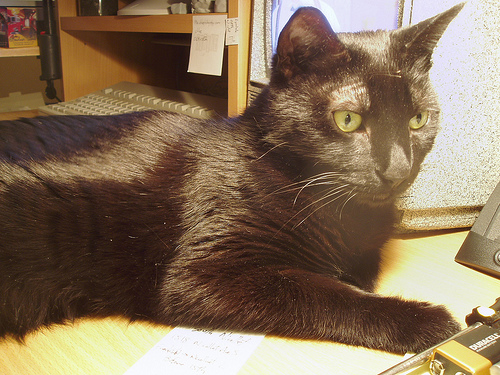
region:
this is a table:
[42, 344, 82, 361]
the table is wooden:
[53, 330, 78, 350]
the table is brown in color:
[56, 345, 88, 362]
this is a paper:
[171, 330, 208, 357]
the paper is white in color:
[153, 353, 163, 364]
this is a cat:
[23, 17, 453, 350]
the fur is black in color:
[132, 141, 221, 212]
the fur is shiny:
[88, 143, 165, 199]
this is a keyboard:
[55, 87, 182, 116]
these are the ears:
[282, 2, 459, 61]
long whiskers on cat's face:
[272, 171, 362, 212]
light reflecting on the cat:
[70, 120, 210, 189]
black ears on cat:
[261, 10, 359, 96]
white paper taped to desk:
[170, 8, 245, 85]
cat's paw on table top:
[359, 283, 457, 357]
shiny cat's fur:
[162, 214, 278, 256]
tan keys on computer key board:
[56, 69, 181, 109]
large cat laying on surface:
[33, 4, 471, 331]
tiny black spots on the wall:
[452, 95, 491, 148]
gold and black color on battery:
[438, 324, 498, 365]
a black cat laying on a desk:
[1, 20, 476, 347]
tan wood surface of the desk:
[44, 330, 105, 369]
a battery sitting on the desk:
[437, 320, 497, 373]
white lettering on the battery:
[466, 330, 497, 352]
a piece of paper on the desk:
[152, 318, 251, 371]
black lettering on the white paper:
[168, 335, 230, 370]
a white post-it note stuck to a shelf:
[177, 8, 234, 81]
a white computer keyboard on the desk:
[51, 78, 227, 138]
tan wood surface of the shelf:
[63, 13, 188, 35]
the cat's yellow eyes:
[324, 90, 435, 146]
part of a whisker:
[296, 158, 346, 218]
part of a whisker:
[308, 176, 350, 212]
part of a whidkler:
[306, 176, 386, 214]